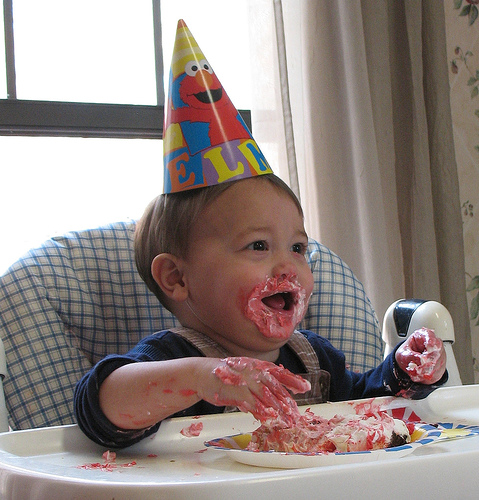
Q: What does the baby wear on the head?
A: Party hat.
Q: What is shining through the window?
A: Light.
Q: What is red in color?
A: Cake.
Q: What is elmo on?
A: On the hat.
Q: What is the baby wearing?
A: Hat.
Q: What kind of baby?
A: Boy.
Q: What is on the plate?
A: Cake.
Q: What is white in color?
A: Table.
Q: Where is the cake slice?
A: On the plate.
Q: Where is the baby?
A: In the high chair.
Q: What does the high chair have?
A: Tray.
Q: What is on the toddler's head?
A: A birthday hat.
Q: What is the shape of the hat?
A: A cone.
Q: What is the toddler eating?
A: Birthday cake.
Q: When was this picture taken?
A: During the birthday party.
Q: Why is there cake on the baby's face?
A: The baby attempts to eat cake.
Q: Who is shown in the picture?
A: A baby.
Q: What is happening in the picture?
A: A birthday celebration for a baby.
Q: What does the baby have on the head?
A: A birthday party hat.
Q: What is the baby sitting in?
A: A chair.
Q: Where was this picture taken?
A: At a birthday party.